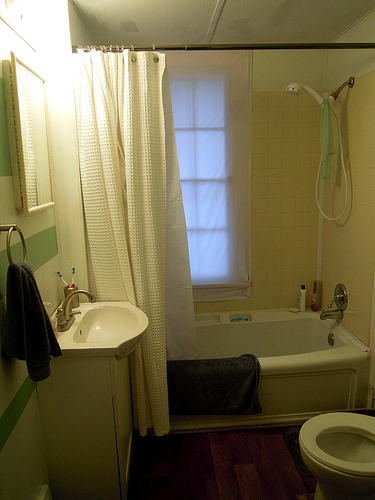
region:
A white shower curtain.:
[70, 46, 198, 437]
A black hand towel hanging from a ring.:
[0, 224, 63, 382]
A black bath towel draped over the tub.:
[166, 353, 262, 416]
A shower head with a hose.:
[284, 81, 348, 221]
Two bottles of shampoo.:
[297, 280, 317, 312]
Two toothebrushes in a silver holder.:
[55, 266, 79, 307]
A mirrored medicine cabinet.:
[0, 51, 54, 215]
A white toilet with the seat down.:
[297, 412, 373, 499]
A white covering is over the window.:
[162, 51, 250, 301]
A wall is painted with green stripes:
[0, 0, 60, 499]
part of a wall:
[267, 172, 291, 215]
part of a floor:
[245, 458, 266, 489]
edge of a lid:
[322, 455, 335, 472]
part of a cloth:
[230, 373, 253, 404]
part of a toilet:
[314, 460, 324, 483]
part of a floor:
[256, 469, 280, 495]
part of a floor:
[256, 444, 276, 498]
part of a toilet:
[299, 441, 320, 476]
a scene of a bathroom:
[2, 0, 372, 498]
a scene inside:
[1, 0, 373, 497]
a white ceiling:
[68, 0, 373, 52]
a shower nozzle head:
[271, 66, 362, 232]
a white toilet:
[286, 388, 373, 496]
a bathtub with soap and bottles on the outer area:
[97, 270, 373, 428]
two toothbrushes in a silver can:
[45, 253, 90, 319]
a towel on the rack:
[0, 223, 84, 386]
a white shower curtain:
[45, 43, 200, 448]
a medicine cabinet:
[1, 50, 69, 218]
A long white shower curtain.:
[73, 49, 184, 437]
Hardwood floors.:
[124, 413, 367, 499]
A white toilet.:
[297, 408, 373, 498]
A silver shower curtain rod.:
[73, 41, 373, 53]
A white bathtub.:
[138, 311, 371, 428]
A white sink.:
[44, 289, 149, 357]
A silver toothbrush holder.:
[63, 287, 81, 306]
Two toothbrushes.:
[54, 263, 78, 289]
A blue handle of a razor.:
[229, 314, 249, 322]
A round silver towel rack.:
[2, 221, 30, 270]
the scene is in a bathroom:
[7, 1, 373, 499]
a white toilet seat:
[300, 419, 373, 492]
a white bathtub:
[261, 310, 352, 400]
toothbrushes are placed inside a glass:
[52, 263, 81, 287]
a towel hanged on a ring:
[8, 239, 65, 378]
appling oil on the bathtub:
[292, 279, 325, 310]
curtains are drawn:
[187, 58, 253, 265]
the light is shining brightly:
[11, 6, 73, 87]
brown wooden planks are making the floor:
[167, 451, 289, 489]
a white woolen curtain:
[99, 115, 169, 231]